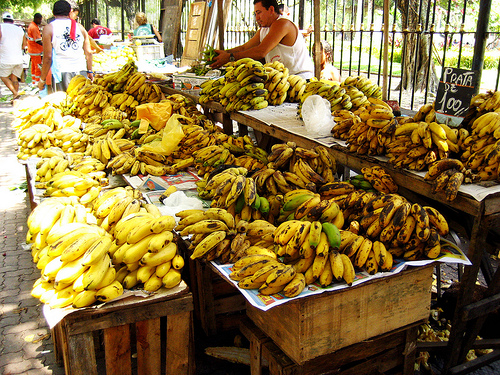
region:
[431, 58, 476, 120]
There is a black price sign near the window.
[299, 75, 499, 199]
There are bananas on the tables.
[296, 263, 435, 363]
The tables are wood.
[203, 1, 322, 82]
A man is taking fruit out of a box.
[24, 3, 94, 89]
People are walking in the background.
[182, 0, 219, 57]
There are tables leaning against the wall.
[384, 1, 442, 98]
A tree is visible from the window.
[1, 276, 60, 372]
The ground is stone.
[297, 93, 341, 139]
There is plastic on one table.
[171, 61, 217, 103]
There is a picture of fruit on the box.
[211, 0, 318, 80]
Man selling bunches of bananas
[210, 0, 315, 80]
Man wearing a white shirt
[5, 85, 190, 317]
Table of yellow ripe bananas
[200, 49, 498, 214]
Bunches of overripe bananas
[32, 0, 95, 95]
Man wearing a white shirt with a bicycle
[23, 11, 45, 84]
Man in orange shirt and pants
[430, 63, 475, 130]
Black sign with white writing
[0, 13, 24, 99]
Man in a white shirt and pants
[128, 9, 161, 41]
Woman in blue with a purse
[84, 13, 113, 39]
Man wearing a red shirt and black hat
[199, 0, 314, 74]
man in white shirt holding bananas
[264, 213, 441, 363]
bananas on wood crate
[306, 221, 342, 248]
green banana by yellow one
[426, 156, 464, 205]
black bananas hanging off table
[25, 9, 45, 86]
man in orange looking at fruit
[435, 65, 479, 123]
black sign with white letter behind bananas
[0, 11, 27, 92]
man in white cap walking away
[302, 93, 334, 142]
plastic bag in front of bananas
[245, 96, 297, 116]
bananas laid on newspapers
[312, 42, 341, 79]
girl watching man in white shirt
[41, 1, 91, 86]
back of man in tank top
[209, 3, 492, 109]
black poles of fence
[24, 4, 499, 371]
outdoor market selling plantains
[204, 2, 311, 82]
man with items in hands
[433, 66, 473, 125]
sign with white numbers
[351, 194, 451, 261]
over ripe dark skin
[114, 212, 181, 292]
yellow skins on plantains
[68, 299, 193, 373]
boards on wood crate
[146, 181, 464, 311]
newspaper on wood boxes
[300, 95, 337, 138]
empty clear plastic bag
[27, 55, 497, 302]
Large outdoor display of bananas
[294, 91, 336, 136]
Plastic bag near bananas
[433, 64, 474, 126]
Black sign on a display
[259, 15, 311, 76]
White shirt on a man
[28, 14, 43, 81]
Man in orange clothes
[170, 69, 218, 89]
Cardboard box with fruit inside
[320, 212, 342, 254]
Green unripe banana in bunch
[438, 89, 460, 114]
White number on a sign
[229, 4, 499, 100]
Metal fence behind bananas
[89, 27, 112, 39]
Red shirt on a man